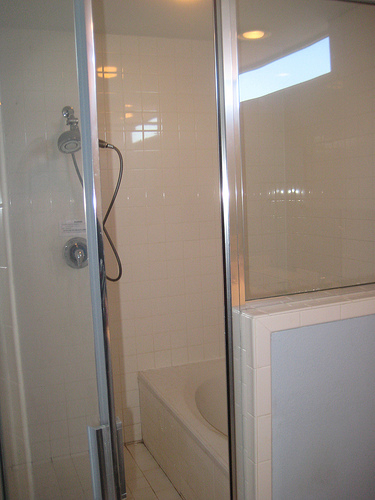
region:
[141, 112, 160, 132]
tile on shower wall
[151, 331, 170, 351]
tile on shower wall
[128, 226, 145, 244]
tile on shower wall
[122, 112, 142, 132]
tile on shower wall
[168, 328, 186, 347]
tile on shower wall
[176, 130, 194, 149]
tile on shower wall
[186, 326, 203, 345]
tile on shower wall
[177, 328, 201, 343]
tile on shower wall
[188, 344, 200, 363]
tile on shower wall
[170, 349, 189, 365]
tile on shower wall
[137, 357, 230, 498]
tan ceramic bath tub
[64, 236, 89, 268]
metal and plastic shower handle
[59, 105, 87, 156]
silver metal shower head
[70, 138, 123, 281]
grey shower head tube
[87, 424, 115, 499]
silver metal door handle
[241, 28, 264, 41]
round light in ceiling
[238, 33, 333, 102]
glass window in bathroom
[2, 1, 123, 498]
glass shower door in bathroom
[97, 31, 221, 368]
white ceramic tiles on wall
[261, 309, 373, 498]
blue painted wall panel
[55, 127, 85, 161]
the shower head in the shower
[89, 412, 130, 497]
the handle to the shwoer door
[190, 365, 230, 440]
the round edge of the bath tub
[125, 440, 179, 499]
gout in the tile by the tub base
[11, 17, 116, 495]
the shower door in the bathroom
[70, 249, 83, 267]
the water nozzle for the shower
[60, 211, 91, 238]
the tag on the wall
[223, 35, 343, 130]
the reflection of the window in the glass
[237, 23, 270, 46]
the light on the ceilng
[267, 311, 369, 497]
the blue part of the half shower wall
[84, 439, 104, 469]
part of a handle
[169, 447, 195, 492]
part of a handle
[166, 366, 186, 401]
part of a glass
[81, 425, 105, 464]
part of a handle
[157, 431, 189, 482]
part of a glass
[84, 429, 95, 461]
part of a handle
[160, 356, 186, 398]
part of a door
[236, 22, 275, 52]
a light on the ceiling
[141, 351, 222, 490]
a tube in the bathroom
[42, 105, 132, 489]
a standing shower in by the tube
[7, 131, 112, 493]
a glass door for the shower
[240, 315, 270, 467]
tile for the walls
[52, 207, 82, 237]
a sticker in the shower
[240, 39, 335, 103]
there is a bathroom window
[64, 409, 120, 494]
a handle on the sliding shower door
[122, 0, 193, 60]
the ceiling has reflection from the light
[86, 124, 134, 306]
a hand held shower head